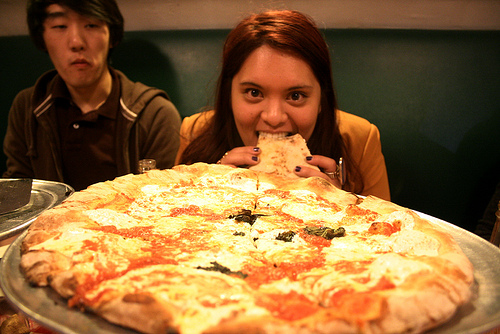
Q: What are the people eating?
A: Pizza.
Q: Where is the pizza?
A: On a tray.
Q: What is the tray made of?
A: Metal.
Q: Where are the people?
A: At a restaurant.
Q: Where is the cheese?
A: On the pizza.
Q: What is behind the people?
A: A wall.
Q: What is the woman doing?
A: Eating pizza.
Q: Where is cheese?
A: On a pizza.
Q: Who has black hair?
A: The man.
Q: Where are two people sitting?
A: In a restaurant booth.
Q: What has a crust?
A: The pizza.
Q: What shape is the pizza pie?
A: Round.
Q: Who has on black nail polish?
A: A woman.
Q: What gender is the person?
A: Female.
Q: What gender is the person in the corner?
A: Male.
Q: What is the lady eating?
A: Pizza.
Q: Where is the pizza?
A: On the pan.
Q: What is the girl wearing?
A: Yellow jacket.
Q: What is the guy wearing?
A: A brown jacket.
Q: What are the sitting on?
A: A bench.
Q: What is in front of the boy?
A: A tin pan.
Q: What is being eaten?
A: Pizza.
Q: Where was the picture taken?
A: In a restaurant.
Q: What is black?
A: Woman's nailpolish.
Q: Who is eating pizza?
A: The woman.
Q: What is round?
A: Pizza pie.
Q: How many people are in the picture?
A: Two.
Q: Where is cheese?
A: On the pizza.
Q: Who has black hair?
A: The man.